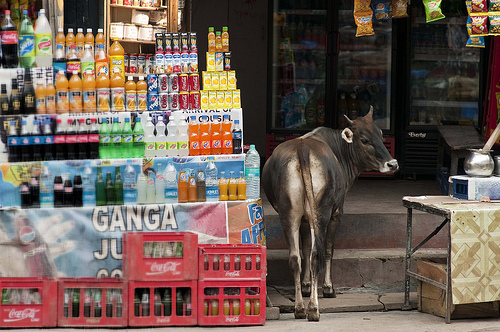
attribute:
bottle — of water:
[245, 142, 261, 197]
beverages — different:
[3, 5, 274, 326]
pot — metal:
[462, 141, 499, 176]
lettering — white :
[90, 199, 182, 232]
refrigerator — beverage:
[265, 12, 444, 140]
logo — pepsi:
[9, 222, 36, 246]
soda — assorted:
[98, 114, 112, 156]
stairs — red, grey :
[322, 197, 430, 285]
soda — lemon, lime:
[98, 112, 110, 157]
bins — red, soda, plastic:
[119, 228, 265, 326]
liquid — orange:
[187, 123, 234, 154]